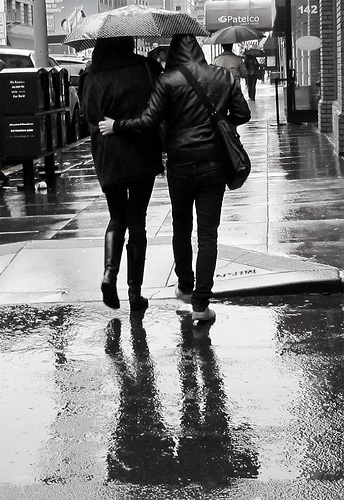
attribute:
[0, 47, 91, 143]
cars — parked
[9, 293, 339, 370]
street — wet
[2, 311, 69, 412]
puddle — water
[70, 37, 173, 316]
person — walking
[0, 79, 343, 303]
sidewalk — wet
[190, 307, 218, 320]
shoe — white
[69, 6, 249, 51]
umbrella — striped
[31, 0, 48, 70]
pole — steel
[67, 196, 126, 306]
boot — leather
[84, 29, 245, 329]
people — stepping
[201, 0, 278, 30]
awning — foreground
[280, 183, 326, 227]
road — behind, soaked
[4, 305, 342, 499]
road — wet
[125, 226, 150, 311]
boot — leather